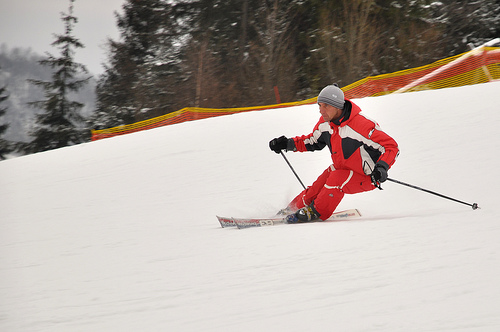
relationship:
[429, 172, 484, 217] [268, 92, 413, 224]
skis on man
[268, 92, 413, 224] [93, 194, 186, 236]
man in snow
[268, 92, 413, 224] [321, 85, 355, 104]
man wearing hat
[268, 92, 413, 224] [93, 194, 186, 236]
man on snow